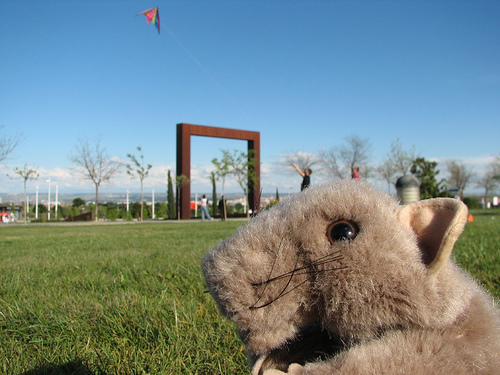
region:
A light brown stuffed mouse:
[202, 184, 499, 374]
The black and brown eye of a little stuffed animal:
[324, 218, 358, 244]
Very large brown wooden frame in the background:
[175, 122, 262, 227]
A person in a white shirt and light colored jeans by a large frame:
[199, 193, 212, 220]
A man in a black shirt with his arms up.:
[288, 160, 313, 190]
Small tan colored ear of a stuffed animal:
[392, 195, 469, 279]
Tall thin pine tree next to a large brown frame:
[166, 170, 177, 221]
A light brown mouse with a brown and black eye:
[201, 180, 498, 373]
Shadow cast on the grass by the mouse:
[15, 362, 93, 374]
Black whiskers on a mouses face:
[247, 235, 351, 313]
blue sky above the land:
[297, 22, 367, 68]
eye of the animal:
[317, 211, 365, 253]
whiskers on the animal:
[262, 253, 325, 296]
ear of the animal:
[407, 177, 480, 267]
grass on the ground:
[115, 286, 156, 311]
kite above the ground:
[133, 5, 169, 34]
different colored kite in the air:
[123, 5, 169, 50]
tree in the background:
[85, 148, 121, 183]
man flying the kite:
[283, 155, 325, 187]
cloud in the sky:
[48, 160, 72, 185]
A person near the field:
[198, 195, 210, 218]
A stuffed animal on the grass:
[207, 180, 497, 374]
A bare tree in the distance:
[76, 141, 114, 221]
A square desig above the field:
[176, 124, 260, 219]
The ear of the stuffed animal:
[398, 200, 470, 268]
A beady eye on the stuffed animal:
[327, 214, 360, 241]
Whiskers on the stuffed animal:
[253, 243, 313, 308]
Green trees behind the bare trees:
[61, 202, 169, 219]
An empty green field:
[3, 225, 498, 370]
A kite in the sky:
[138, 7, 162, 33]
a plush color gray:
[185, 165, 497, 365]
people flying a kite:
[123, 0, 370, 196]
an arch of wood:
[156, 115, 268, 223]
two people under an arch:
[165, 111, 265, 224]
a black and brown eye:
[316, 206, 366, 256]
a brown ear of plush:
[393, 183, 478, 294]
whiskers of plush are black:
[233, 232, 351, 327]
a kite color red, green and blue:
[136, 5, 175, 40]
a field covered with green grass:
[14, 125, 485, 374]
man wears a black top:
[290, 155, 317, 191]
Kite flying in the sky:
[128, 3, 164, 36]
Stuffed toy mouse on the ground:
[190, 172, 498, 374]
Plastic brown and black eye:
[322, 213, 362, 248]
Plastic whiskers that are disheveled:
[246, 235, 355, 310]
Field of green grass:
[0, 210, 498, 372]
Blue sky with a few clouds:
[1, 0, 498, 191]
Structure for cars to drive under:
[170, 119, 265, 225]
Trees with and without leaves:
[0, 120, 498, 222]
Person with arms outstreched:
[284, 154, 314, 194]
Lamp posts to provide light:
[30, 174, 63, 226]